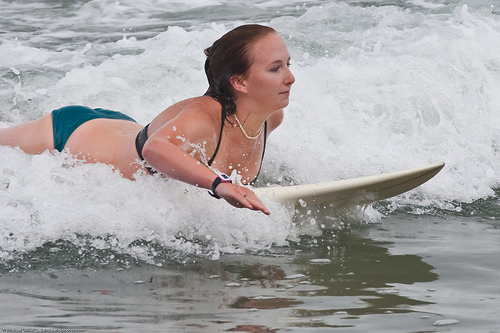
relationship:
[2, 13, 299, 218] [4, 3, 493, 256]
woman riding waves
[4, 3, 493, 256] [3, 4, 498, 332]
waves are in ocean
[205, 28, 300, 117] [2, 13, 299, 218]
head of a woman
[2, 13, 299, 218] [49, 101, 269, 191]
woman in a bikini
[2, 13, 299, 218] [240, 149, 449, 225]
woman lying on a surfboard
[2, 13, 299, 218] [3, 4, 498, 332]
woman at beach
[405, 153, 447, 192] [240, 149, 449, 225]
front of surfboard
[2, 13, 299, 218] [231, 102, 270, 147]
woman wearing a necklace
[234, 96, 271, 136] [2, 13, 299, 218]
neck of woman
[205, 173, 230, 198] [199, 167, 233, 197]
wrist on wrist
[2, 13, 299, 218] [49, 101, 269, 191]
woman wearing bikini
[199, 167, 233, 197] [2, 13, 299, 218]
right wrist of woman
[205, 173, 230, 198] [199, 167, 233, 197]
wrist on right wrist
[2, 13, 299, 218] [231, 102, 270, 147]
woman wearing chain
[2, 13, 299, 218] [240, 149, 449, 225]
woman on a surfboard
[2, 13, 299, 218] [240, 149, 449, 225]
woman laying on surfboard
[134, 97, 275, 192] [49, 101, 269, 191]
top of bikini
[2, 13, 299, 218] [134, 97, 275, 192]
woman wearing top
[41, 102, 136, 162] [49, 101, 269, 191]
bottoms of bikini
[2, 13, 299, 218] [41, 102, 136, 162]
woman wearing bottoms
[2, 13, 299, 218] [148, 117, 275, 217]
woman paddling with her arms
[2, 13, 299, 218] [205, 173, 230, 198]
woman wearing wrist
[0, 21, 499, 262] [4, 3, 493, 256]
foam on waves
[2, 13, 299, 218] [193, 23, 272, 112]
woman with hair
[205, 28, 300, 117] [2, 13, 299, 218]
head of woman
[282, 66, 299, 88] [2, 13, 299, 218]
nose of woman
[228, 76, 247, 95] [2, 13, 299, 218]
ear of woman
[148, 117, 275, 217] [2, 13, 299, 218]
arm of woman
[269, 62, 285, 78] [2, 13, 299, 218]
eye of woman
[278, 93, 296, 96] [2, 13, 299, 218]
mouth of woman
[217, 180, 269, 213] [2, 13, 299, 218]
hand of woman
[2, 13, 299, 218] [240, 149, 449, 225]
woman riding surfboard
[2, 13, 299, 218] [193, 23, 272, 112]
woman has hair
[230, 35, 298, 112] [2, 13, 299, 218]
face of woman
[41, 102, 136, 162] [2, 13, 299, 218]
rear end of woman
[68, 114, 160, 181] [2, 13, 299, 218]
torso of woman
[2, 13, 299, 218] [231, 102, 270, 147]
woman wearing necklace